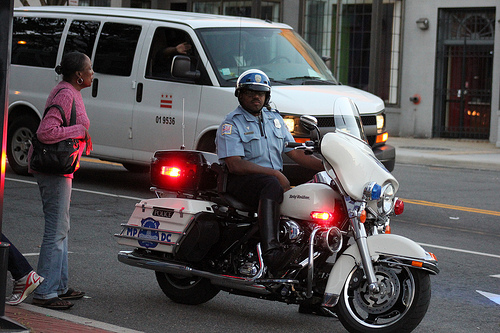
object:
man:
[209, 62, 327, 274]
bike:
[108, 92, 441, 332]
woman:
[23, 45, 103, 311]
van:
[5, 5, 399, 195]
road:
[0, 148, 499, 331]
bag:
[27, 86, 89, 177]